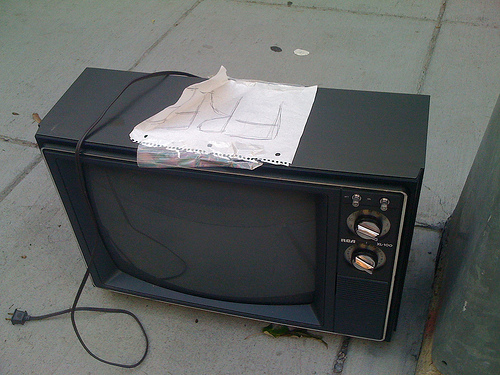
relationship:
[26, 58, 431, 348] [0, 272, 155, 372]
television has cable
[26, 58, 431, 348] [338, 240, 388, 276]
television has knob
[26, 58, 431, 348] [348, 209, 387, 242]
television has knob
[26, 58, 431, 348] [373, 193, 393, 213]
television has tuning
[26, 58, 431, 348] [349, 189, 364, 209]
television has tuning knob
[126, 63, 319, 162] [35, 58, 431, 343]
sign on television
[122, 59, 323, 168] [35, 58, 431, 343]
paper on television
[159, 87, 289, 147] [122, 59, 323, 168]
writing on paper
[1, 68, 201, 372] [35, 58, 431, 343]
cord on television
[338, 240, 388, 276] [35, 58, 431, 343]
knob on television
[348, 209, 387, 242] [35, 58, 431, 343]
knob on television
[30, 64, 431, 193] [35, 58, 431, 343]
frame for television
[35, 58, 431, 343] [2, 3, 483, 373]
television on sidewalk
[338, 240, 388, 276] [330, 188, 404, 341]
knob on control panel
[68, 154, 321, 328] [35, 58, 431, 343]
screen on television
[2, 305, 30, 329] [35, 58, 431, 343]
plug for television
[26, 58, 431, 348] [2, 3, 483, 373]
television on sidewalk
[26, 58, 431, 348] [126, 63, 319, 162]
television with sign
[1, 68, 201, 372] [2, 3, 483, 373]
cord on sidewalk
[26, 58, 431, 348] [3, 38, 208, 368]
television has cord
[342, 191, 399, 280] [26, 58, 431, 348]
controls on television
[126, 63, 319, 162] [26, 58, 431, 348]
sign on television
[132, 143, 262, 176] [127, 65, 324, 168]
tape attaching paper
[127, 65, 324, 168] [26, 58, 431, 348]
paper attached to television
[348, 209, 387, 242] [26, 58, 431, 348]
knob on television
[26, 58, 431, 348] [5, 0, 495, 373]
television on ground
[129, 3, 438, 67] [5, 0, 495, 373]
concrete square on ground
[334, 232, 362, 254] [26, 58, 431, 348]
writing on television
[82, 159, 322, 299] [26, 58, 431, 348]
glass on television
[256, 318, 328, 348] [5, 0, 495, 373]
leaf on ground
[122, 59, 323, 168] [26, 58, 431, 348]
paper taped to television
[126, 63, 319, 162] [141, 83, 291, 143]
sign says free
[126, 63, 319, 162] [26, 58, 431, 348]
sign on top of television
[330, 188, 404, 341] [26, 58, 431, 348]
control panel on television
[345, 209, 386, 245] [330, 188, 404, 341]
dial on control panel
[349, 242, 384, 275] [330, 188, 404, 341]
dial on control panel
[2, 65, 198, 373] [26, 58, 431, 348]
electrical cord attached to television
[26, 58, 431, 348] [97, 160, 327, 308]
television has screen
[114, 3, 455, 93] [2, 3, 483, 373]
section of sidewalk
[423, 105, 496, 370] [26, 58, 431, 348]
wall beside television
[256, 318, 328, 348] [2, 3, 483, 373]
leaf lying on sidewalk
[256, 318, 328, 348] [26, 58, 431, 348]
leaf in front of television